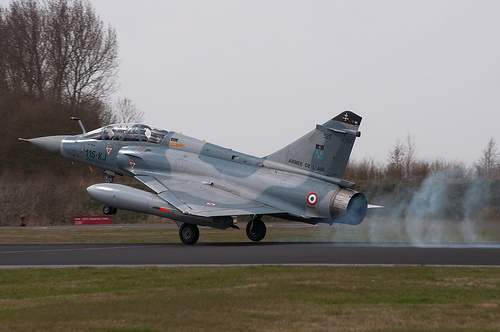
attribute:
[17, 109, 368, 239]
jet — tan, green, gra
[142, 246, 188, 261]
runway — gray, asphalt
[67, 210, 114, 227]
structure — red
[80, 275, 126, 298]
grass — green, brown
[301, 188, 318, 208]
marks — red, white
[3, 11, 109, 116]
tree — large, tall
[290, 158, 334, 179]
writing — black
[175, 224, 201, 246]
wheel — black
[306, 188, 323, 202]
circle — blue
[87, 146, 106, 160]
letterig — black, 115-kj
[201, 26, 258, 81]
sky — clear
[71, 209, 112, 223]
sign — red